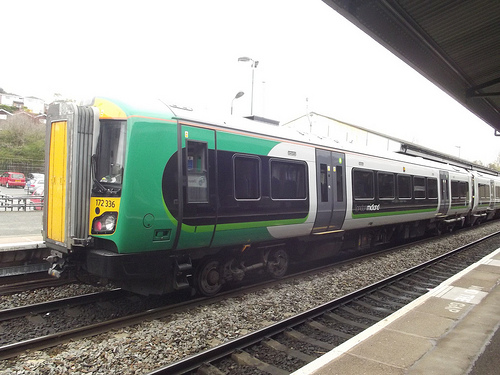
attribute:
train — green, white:
[27, 95, 499, 303]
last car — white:
[468, 153, 499, 228]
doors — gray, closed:
[314, 139, 350, 243]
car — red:
[0, 166, 28, 194]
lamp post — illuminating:
[232, 50, 268, 114]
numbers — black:
[92, 196, 118, 213]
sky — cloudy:
[3, 2, 487, 136]